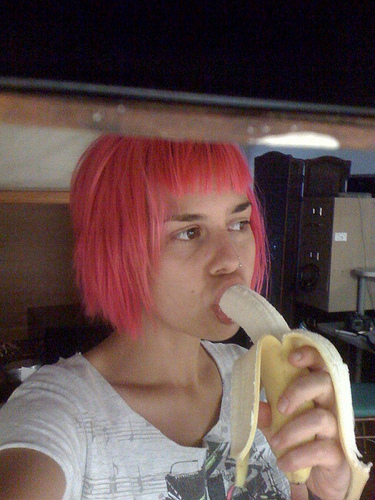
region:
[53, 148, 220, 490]
the lady is motionless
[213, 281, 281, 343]
this is a banana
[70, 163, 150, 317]
this is the hair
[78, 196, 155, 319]
the hair is red in color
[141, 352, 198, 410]
the lady is light skinned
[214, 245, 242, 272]
this is the nose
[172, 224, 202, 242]
this is the eye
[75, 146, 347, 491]
a person eatinging a banana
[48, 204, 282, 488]
a person with an open banana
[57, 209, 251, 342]
a person with pink hair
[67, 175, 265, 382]
a person with mouth around banana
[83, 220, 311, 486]
a person wearing a shirt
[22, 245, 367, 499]
a person wearing a white shirt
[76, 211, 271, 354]
a person with a nose stud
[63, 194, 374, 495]
a person that is inside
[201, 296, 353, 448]
a banana that is peeled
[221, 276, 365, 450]
a banana that is peeled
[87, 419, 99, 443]
music note on shirt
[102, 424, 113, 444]
music note on shirt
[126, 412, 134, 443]
music note on shirt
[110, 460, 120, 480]
music note on shirt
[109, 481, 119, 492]
music note on shirt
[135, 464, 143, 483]
music note on shirt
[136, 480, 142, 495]
music note on shirt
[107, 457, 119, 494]
music notes on shirt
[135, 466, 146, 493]
music notes on shirt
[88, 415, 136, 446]
music notes on shirt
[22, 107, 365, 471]
a girl eating a banana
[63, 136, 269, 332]
the head of a girl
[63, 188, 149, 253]
the pink hair of a girl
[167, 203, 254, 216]
the eyebrows of a girl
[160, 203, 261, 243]
the eyes of a girl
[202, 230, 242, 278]
the nose of a girl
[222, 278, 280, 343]
the fruit part of a banana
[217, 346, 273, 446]
the peel of a banana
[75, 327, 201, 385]
the neck of a girl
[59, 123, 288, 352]
pink hair on the head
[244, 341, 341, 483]
fingers curled over a banana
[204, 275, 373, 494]
banana sticking in the mouth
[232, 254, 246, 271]
piercing on the nose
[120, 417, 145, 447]
music note on the shirt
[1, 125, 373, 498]
woman eating a banana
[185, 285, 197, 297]
freckle on the face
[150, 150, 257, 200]
bangs laying on the forehead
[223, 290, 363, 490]
A peeled banana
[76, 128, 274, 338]
A woman sucking a banana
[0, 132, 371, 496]
A woman eating a banana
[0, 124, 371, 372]
A woman with pink colored hair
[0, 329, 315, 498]
A t-shirt with a design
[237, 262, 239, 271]
a stud in the nose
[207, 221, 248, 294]
a nose on the person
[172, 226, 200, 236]
eye on the person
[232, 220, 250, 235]
an eye on the person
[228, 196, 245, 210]
an eyebrow on the person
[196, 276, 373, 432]
a banana is half way peeled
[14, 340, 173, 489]
a white shirt ont he person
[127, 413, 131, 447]
a music note on the shirt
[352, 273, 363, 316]
A silver metal pole.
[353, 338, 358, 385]
A silver metal pole.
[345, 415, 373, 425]
A silver metal pole.